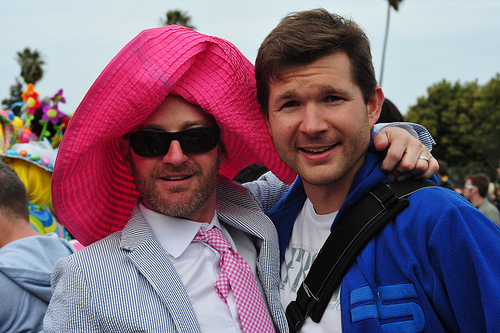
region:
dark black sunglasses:
[118, 120, 215, 162]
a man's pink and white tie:
[190, 230, 273, 331]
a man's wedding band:
[413, 152, 437, 163]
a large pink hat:
[52, 21, 299, 250]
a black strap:
[283, 170, 429, 330]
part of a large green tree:
[397, 75, 498, 182]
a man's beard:
[124, 153, 222, 215]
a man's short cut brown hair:
[257, 10, 380, 116]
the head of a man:
[462, 169, 490, 201]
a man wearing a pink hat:
[89, 54, 254, 242]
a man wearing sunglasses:
[105, 104, 230, 187]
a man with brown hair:
[256, 13, 386, 125]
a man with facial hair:
[128, 155, 230, 218]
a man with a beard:
[111, 168, 224, 224]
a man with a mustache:
[134, 157, 218, 194]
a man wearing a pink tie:
[196, 205, 251, 331]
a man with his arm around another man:
[166, 106, 447, 263]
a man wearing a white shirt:
[161, 212, 249, 331]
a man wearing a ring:
[411, 141, 442, 178]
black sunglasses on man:
[120, 120, 230, 162]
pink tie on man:
[195, 220, 275, 332]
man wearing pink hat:
[51, 9, 275, 331]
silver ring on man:
[417, 150, 432, 166]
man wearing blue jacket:
[246, 0, 498, 330]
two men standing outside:
[70, 9, 440, 331]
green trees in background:
[398, 57, 499, 193]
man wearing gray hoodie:
[1, 164, 77, 331]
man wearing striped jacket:
[56, 10, 281, 331]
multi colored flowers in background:
[0, 68, 65, 176]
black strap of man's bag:
[278, 163, 423, 330]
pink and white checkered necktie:
[199, 219, 271, 331]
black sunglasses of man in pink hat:
[124, 125, 212, 161]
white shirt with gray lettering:
[283, 204, 355, 331]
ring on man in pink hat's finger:
[418, 147, 433, 162]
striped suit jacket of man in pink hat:
[56, 119, 435, 329]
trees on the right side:
[403, 67, 499, 184]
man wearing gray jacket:
[1, 166, 77, 331]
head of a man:
[241, 15, 391, 204]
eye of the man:
[311, 77, 356, 122]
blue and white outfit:
[305, 272, 389, 332]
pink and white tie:
[195, 229, 260, 331]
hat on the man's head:
[36, 48, 211, 170]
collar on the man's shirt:
[154, 200, 236, 256]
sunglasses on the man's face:
[123, 97, 227, 168]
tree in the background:
[414, 78, 493, 141]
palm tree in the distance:
[11, 40, 66, 87]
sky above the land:
[53, 14, 99, 50]